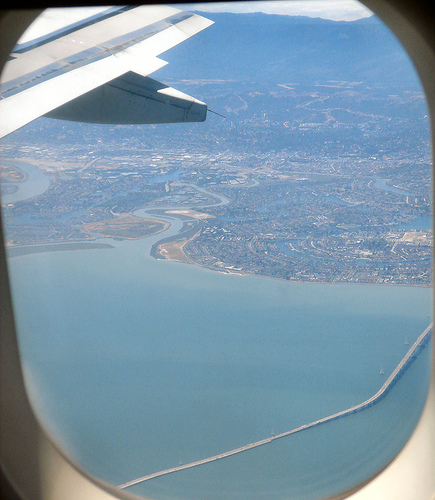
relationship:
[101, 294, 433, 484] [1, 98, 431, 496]
bridge crossing water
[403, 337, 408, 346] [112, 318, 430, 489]
boat beside bridge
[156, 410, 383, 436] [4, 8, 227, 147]
partial wing of airplane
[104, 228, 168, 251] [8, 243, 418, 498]
mouth on river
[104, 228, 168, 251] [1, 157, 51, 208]
mouth on river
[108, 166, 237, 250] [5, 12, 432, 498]
river out window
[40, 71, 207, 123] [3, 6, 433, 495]
housing on airplane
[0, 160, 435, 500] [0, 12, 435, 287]
water surrounding land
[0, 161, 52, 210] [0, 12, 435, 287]
water surrounding land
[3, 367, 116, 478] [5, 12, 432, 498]
frame on window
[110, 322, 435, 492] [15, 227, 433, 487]
bridge across river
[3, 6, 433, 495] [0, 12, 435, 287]
airplane above land